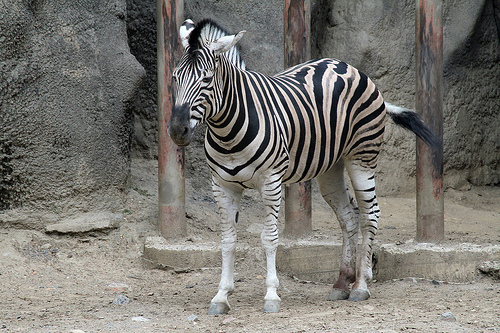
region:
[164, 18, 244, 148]
Head of the zebra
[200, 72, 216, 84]
left eye of the zebra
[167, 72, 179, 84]
right eye of the zebra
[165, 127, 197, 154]
mouth of the zebra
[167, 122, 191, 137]
nose of the zebra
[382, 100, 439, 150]
Tail of the zebra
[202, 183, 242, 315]
right leg of the zebra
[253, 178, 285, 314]
left leg of the zebra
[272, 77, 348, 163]
Black and white stripes of the body of the zebra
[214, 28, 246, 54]
left ear of the zebra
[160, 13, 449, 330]
This is a zebra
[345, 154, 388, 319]
Leg of a zebra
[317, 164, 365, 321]
Leg of a zebra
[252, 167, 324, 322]
Leg of a zebra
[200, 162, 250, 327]
Leg of a zebra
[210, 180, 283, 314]
The front legs of the zebra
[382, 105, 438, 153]
The tail of the zebra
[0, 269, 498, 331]
The ground beneath the zebra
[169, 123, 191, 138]
The nose of the zebra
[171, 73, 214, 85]
The eyes of the zebra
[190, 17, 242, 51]
The mane of the zebra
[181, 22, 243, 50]
The ears of the zebra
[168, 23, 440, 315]
A zebra standing on the ground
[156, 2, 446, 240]
Three wooden poles behind the zebra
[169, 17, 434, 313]
The zebra has black and white stripes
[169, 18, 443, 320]
this is a zebra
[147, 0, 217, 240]
this is a pole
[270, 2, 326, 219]
this is a pole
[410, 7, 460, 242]
this is a pole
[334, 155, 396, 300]
the leg of a zebra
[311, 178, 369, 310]
the leg of a zebra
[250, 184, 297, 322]
the leg of a zebra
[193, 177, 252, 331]
the leg of a zebra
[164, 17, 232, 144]
the head of a zebra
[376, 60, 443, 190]
thetail of a zebra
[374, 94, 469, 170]
black tail of zebra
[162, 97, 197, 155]
black nose of zebra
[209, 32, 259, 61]
this is a white ear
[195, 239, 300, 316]
white legs of zebra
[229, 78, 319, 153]
black stripes on zebra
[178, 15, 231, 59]
striped mane of zebra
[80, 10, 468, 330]
zebra standing in dirt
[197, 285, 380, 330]
grey feet of zebra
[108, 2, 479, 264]
poles behind the zebra